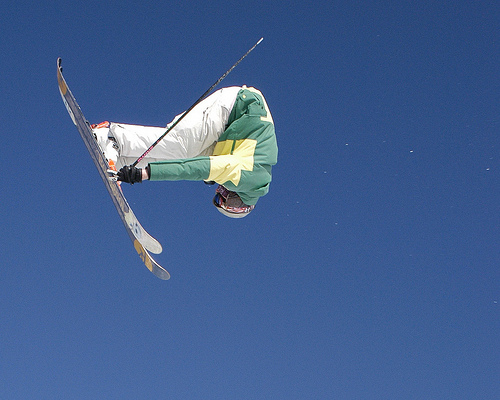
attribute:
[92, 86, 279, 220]
man — jumping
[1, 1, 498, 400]
air — blue, here, clear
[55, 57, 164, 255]
ski — here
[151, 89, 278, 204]
jacket — green, yellow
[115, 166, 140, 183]
glove — black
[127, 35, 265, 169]
pole — here, black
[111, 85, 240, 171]
pants — white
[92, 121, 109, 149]
shoe — white